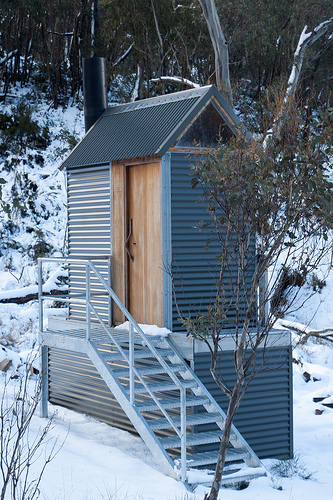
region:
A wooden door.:
[117, 163, 163, 326]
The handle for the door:
[122, 218, 139, 258]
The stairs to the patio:
[92, 338, 249, 484]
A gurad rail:
[37, 258, 90, 321]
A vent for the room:
[81, 54, 107, 130]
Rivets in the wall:
[105, 396, 118, 429]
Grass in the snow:
[272, 451, 316, 479]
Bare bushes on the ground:
[1, 339, 55, 498]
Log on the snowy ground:
[2, 277, 34, 314]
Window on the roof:
[176, 96, 248, 160]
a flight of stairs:
[120, 305, 228, 498]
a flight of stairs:
[126, 291, 186, 479]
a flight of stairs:
[173, 349, 227, 470]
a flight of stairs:
[171, 402, 209, 494]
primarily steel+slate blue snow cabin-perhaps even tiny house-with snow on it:
[29, 43, 306, 498]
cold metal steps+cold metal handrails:
[32, 254, 290, 498]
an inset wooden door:
[111, 159, 161, 325]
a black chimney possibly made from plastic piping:
[75, 51, 115, 137]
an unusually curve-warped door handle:
[119, 216, 139, 266]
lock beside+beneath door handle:
[129, 240, 139, 249]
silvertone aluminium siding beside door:
[68, 162, 110, 322]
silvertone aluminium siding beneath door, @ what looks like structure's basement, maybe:
[42, 334, 190, 457]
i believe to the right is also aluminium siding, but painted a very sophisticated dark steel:
[162, 149, 290, 460]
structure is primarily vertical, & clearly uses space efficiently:
[29, 45, 302, 497]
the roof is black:
[46, 82, 270, 178]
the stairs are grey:
[31, 254, 272, 489]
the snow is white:
[176, 460, 269, 493]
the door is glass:
[104, 151, 129, 330]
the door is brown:
[118, 160, 172, 341]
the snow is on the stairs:
[162, 451, 274, 492]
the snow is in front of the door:
[111, 313, 173, 351]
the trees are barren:
[0, 0, 331, 499]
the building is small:
[38, 54, 296, 493]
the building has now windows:
[37, 49, 300, 493]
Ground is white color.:
[62, 446, 117, 484]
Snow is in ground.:
[82, 434, 130, 492]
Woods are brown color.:
[66, 9, 292, 53]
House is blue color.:
[66, 194, 235, 318]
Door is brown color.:
[111, 219, 176, 282]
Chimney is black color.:
[75, 49, 116, 108]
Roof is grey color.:
[95, 116, 166, 142]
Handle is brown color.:
[114, 223, 145, 261]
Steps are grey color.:
[108, 355, 200, 435]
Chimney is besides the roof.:
[73, 52, 128, 129]